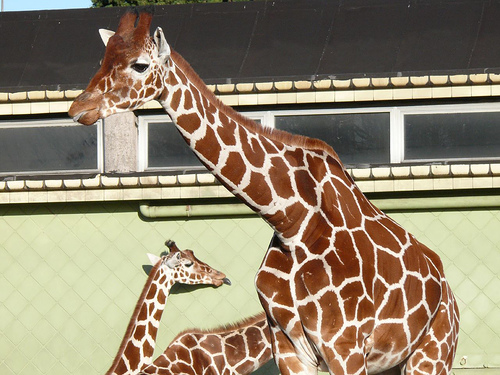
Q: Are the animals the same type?
A: Yes, all the animals are giraffes.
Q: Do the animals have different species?
A: No, all the animals are giraffes.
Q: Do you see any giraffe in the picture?
A: Yes, there is a giraffe.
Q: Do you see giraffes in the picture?
A: Yes, there is a giraffe.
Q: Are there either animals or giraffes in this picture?
A: Yes, there is a giraffe.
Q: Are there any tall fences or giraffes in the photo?
A: Yes, there is a tall giraffe.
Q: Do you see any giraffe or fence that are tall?
A: Yes, the giraffe is tall.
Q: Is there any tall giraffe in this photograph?
A: Yes, there is a tall giraffe.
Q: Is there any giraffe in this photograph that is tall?
A: Yes, there is a giraffe that is tall.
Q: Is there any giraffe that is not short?
A: Yes, there is a tall giraffe.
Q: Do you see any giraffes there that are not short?
A: Yes, there is a tall giraffe.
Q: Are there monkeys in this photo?
A: No, there are no monkeys.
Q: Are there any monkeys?
A: No, there are no monkeys.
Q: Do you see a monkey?
A: No, there are no monkeys.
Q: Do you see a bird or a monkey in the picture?
A: No, there are no monkeys or birds.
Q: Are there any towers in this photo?
A: No, there are no towers.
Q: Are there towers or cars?
A: No, there are no towers or cars.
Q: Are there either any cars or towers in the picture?
A: No, there are no towers or cars.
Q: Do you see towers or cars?
A: No, there are no towers or cars.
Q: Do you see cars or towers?
A: No, there are no towers or cars.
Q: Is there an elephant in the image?
A: No, there are no elephants.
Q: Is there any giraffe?
A: Yes, there is a giraffe.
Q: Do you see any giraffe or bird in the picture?
A: Yes, there is a giraffe.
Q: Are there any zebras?
A: No, there are no zebras.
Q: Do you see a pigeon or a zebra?
A: No, there are no zebras or pigeons.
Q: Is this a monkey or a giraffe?
A: This is a giraffe.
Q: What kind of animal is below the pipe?
A: The animal is a giraffe.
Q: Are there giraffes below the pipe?
A: Yes, there is a giraffe below the pipe.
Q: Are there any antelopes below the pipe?
A: No, there is a giraffe below the pipe.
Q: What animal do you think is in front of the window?
A: The giraffe is in front of the window.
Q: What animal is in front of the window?
A: The giraffe is in front of the window.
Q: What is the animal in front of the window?
A: The animal is a giraffe.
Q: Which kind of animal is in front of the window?
A: The animal is a giraffe.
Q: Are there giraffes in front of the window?
A: Yes, there is a giraffe in front of the window.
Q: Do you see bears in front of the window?
A: No, there is a giraffe in front of the window.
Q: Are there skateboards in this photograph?
A: No, there are no skateboards.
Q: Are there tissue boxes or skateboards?
A: No, there are no skateboards or tissue boxes.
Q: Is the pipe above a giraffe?
A: Yes, the pipe is above a giraffe.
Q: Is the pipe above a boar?
A: No, the pipe is above a giraffe.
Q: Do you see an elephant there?
A: No, there are no elephants.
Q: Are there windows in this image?
A: Yes, there is a window.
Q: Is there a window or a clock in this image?
A: Yes, there is a window.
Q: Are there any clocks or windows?
A: Yes, there is a window.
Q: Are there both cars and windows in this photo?
A: No, there is a window but no cars.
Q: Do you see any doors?
A: No, there are no doors.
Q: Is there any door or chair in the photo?
A: No, there are no doors or chairs.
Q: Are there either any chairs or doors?
A: No, there are no doors or chairs.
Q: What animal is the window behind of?
A: The window is behind the giraffe.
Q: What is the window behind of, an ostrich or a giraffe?
A: The window is behind a giraffe.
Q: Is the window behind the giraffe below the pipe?
A: Yes, the window is behind the giraffe.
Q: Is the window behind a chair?
A: No, the window is behind the giraffe.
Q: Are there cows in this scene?
A: No, there are no cows.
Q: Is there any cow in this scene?
A: No, there are no cows.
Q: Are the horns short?
A: Yes, the horns are short.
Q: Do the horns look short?
A: Yes, the horns are short.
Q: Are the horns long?
A: No, the horns are short.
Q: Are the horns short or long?
A: The horns are short.